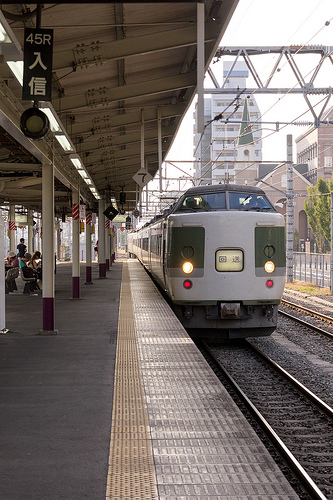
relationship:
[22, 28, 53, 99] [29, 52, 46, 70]
sign with symbol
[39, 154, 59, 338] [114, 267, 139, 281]
metal post in pavement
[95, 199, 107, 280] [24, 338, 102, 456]
metal post in pavement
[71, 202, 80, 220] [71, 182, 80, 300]
patch on metal post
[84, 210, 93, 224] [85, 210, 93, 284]
patch on pole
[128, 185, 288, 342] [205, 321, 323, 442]
train on tracks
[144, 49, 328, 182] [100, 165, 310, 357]
wires above train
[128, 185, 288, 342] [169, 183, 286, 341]
train has front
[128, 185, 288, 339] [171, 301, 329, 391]
train on track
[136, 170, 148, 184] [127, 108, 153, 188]
number 7 on sign post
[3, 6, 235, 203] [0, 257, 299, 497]
awning sheltering platform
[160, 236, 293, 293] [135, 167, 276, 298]
light on train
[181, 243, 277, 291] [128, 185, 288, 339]
light on train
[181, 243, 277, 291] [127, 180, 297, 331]
light on train